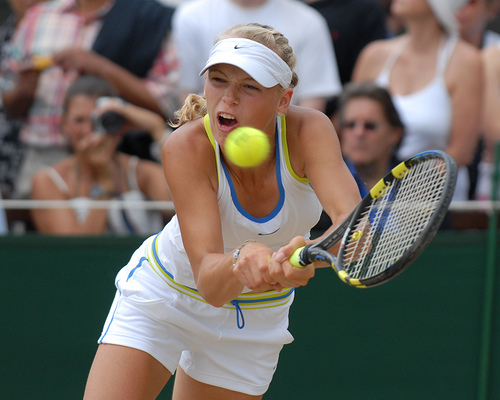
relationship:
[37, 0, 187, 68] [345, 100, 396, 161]
man has face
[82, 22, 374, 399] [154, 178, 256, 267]
player has arm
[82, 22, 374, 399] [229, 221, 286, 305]
player has hand